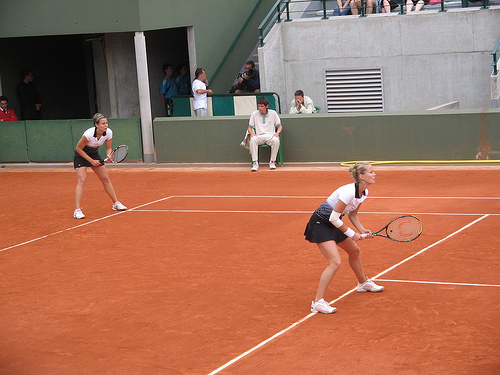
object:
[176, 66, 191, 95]
man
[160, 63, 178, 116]
man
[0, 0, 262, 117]
wall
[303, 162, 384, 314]
person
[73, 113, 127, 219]
person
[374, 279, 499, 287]
white line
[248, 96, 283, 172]
linesman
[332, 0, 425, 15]
legs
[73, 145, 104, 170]
skirt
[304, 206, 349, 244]
skirt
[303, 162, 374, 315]
blonde woman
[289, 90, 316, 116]
man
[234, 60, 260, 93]
man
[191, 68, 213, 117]
man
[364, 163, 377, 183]
face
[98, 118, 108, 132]
face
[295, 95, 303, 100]
face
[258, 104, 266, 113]
face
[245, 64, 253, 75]
face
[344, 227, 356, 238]
wristband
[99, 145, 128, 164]
racket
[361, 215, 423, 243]
racket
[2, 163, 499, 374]
clay court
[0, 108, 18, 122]
red jacket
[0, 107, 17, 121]
coat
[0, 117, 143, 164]
wall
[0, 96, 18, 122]
man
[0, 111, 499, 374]
tennis match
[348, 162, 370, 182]
hair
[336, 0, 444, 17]
people